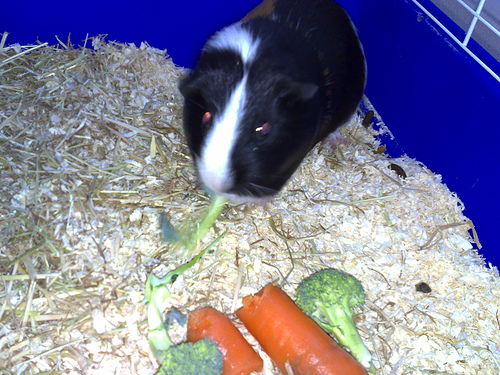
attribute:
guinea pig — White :
[178, 1, 365, 204]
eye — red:
[256, 121, 271, 136]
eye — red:
[200, 112, 211, 122]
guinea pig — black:
[176, 66, 320, 202]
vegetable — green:
[178, 192, 225, 249]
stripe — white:
[194, 85, 251, 193]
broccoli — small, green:
[292, 267, 376, 367]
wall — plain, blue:
[1, 0, 498, 272]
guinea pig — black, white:
[155, 0, 405, 211]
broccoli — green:
[288, 262, 381, 373]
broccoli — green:
[135, 282, 230, 373]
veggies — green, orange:
[120, 247, 382, 373]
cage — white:
[8, 2, 495, 322]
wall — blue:
[409, 64, 474, 156]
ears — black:
[165, 71, 332, 110]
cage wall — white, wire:
[408, 0, 497, 87]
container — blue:
[368, 10, 483, 224]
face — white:
[197, 100, 273, 181]